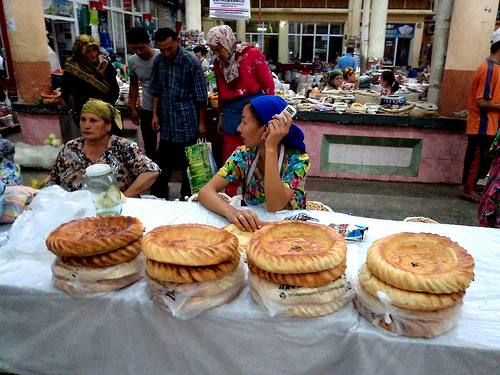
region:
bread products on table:
[47, 215, 474, 335]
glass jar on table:
[81, 163, 124, 215]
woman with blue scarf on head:
[199, 94, 311, 233]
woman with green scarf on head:
[51, 100, 159, 199]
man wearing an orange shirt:
[462, 28, 499, 196]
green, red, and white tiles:
[293, 118, 466, 183]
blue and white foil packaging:
[325, 221, 367, 241]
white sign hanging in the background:
[210, 0, 252, 20]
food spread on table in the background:
[289, 98, 439, 118]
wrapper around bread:
[51, 263, 141, 298]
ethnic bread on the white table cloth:
[46, 215, 144, 252]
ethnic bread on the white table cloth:
[54, 240, 142, 266]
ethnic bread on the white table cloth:
[138, 223, 238, 265]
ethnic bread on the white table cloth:
[145, 257, 242, 282]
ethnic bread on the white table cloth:
[251, 219, 346, 271]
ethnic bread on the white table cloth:
[365, 232, 477, 291]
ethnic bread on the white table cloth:
[355, 263, 465, 307]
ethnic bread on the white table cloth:
[247, 258, 346, 285]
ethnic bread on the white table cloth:
[245, 290, 350, 321]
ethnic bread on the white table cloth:
[353, 295, 463, 341]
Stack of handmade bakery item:
[245, 218, 355, 315]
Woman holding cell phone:
[197, 96, 311, 233]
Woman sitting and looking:
[45, 98, 160, 196]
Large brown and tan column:
[3, 0, 53, 100]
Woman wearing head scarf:
[201, 21, 271, 191]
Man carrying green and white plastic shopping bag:
[145, 25, 215, 196]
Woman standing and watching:
[60, 30, 115, 135]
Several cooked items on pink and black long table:
[11, 85, 466, 185]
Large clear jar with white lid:
[80, 160, 121, 215]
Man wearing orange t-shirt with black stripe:
[458, 25, 498, 205]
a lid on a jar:
[83, 159, 114, 182]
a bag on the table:
[333, 204, 374, 248]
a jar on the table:
[84, 159, 144, 219]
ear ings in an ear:
[257, 128, 270, 151]